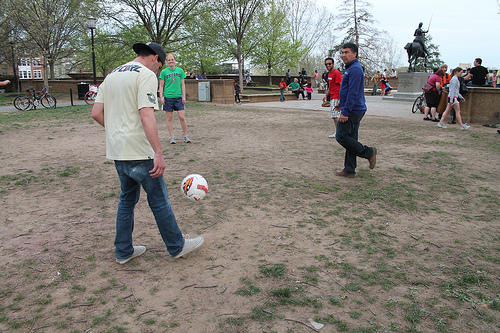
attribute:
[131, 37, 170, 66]
hat — dark blue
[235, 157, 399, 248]
grass — green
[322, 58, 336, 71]
face — man's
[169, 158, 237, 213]
soccer game — pickup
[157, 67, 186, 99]
shirt — green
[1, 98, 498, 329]
dirt — patch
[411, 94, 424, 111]
tire — bike's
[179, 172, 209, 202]
ball — soccer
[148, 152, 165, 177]
hand — man's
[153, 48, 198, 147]
soccer player — pickup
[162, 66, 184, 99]
shirt — green, t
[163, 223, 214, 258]
shoe — white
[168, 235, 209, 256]
shoe — white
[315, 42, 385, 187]
players — pickup, soccer, more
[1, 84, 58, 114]
bike — in background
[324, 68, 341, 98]
t-shirt — red, t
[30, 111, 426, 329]
area — sad, grassy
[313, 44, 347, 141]
player — soccer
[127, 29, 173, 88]
head — man's